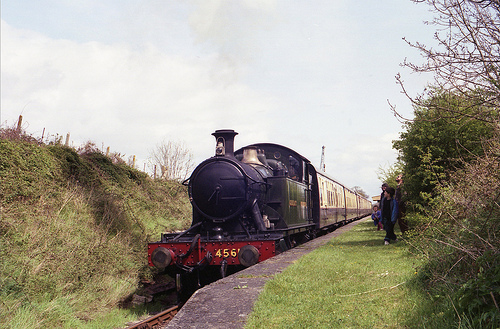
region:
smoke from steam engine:
[188, 1, 280, 156]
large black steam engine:
[131, 120, 319, 307]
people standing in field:
[359, 174, 421, 256]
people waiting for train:
[111, 116, 453, 327]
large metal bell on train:
[234, 138, 266, 179]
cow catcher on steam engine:
[123, 228, 281, 327]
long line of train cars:
[311, 159, 378, 243]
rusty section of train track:
[113, 291, 208, 327]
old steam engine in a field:
[6, 5, 488, 324]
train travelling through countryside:
[1, 7, 485, 321]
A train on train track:
[94, 108, 371, 307]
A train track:
[116, 298, 189, 328]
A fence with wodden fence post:
[4, 106, 184, 180]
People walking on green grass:
[372, 172, 412, 248]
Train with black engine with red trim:
[139, 111, 369, 281]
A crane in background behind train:
[314, 140, 344, 175]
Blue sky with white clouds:
[6, 5, 417, 182]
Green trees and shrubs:
[394, 5, 499, 320]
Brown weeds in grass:
[13, 176, 140, 284]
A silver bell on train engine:
[240, 144, 269, 172]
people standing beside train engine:
[356, 176, 406, 248]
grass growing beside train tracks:
[296, 268, 357, 324]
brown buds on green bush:
[446, 161, 494, 212]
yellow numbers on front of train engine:
[210, 245, 245, 257]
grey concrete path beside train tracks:
[207, 288, 249, 324]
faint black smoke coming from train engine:
[192, 7, 275, 102]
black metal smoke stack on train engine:
[199, 122, 241, 159]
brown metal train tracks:
[144, 308, 168, 327]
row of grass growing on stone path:
[234, 270, 266, 282]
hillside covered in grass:
[9, 121, 121, 312]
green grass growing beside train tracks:
[309, 254, 359, 299]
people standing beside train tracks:
[361, 171, 408, 246]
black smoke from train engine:
[184, 0, 272, 97]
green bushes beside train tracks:
[421, 154, 498, 325]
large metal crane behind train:
[314, 136, 334, 176]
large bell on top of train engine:
[234, 140, 268, 174]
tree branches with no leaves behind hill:
[149, 131, 191, 179]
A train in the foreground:
[142, 116, 385, 289]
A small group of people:
[364, 174, 416, 249]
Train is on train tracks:
[101, 247, 197, 326]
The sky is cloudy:
[6, 11, 497, 164]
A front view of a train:
[117, 115, 343, 306]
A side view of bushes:
[395, 77, 495, 322]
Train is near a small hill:
[6, 114, 218, 263]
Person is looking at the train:
[374, 185, 404, 242]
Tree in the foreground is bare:
[406, 3, 499, 95]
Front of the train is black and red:
[138, 122, 330, 286]